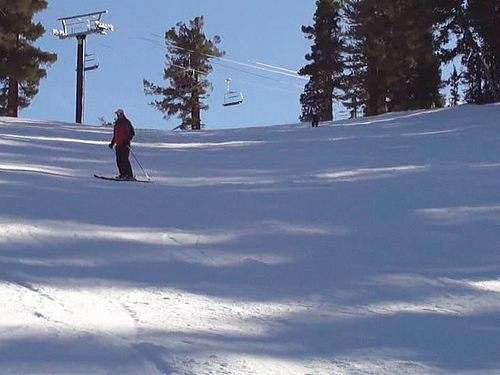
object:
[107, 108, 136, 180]
skier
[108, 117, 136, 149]
red jacket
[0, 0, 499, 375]
day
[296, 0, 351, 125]
trees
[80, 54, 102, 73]
ski lift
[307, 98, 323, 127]
skier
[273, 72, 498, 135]
distance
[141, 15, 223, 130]
tree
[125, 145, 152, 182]
ski poles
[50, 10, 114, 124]
pole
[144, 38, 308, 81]
wires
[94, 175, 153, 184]
skis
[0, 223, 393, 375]
tracks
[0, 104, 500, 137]
top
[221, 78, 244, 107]
ski chair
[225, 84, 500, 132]
mountain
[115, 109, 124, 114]
white cap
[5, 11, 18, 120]
poles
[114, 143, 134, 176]
pants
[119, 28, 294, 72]
wires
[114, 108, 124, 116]
cap and glasses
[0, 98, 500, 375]
shadow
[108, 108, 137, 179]
suit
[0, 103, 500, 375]
field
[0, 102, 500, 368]
slope